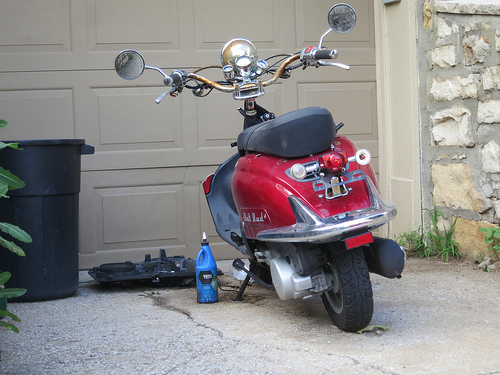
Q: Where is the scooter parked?
A: Driveway.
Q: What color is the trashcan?
A: Black.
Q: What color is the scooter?
A: Red.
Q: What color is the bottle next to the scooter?
A: Blue.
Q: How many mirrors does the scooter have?
A: Two.